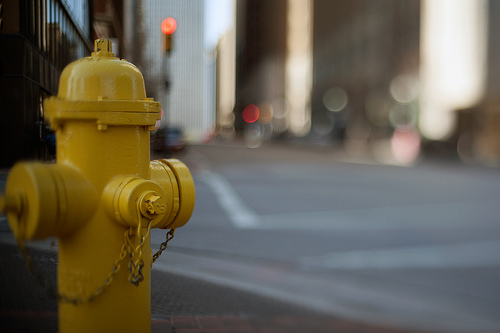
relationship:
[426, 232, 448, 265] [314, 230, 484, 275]
part of a line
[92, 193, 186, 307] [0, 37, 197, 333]
chain hanging from fire hydrant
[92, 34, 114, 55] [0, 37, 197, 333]
top of fire hydrant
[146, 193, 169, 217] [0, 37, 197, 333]
bolt of fire hydrant